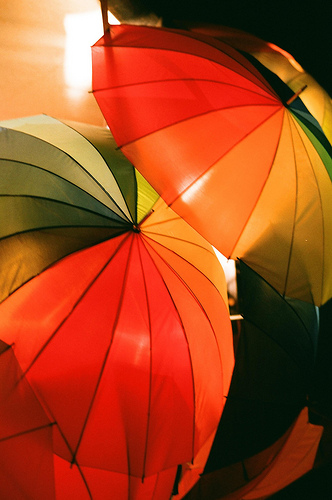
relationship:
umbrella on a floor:
[92, 23, 331, 306] [184, 409, 328, 499]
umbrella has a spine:
[92, 23, 331, 306] [136, 208, 154, 230]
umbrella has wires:
[92, 23, 331, 306] [115, 101, 282, 155]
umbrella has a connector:
[92, 23, 331, 306] [284, 82, 306, 108]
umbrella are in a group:
[92, 23, 331, 306] [3, 23, 329, 500]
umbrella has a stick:
[92, 23, 331, 306] [287, 83, 309, 109]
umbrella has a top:
[92, 23, 331, 306] [285, 83, 304, 106]